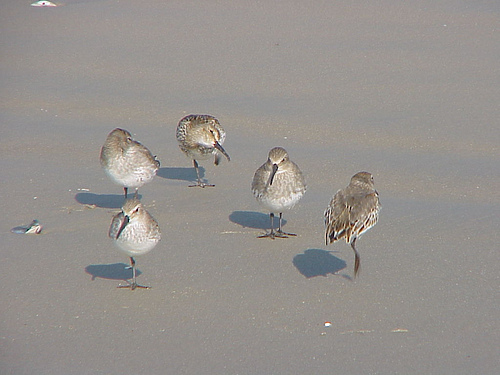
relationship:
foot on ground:
[198, 175, 231, 194] [36, 40, 496, 359]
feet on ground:
[244, 214, 291, 237] [36, 40, 496, 359]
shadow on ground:
[226, 193, 287, 244] [36, 40, 496, 359]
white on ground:
[317, 315, 402, 367] [36, 40, 496, 359]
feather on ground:
[19, 198, 64, 244] [36, 40, 496, 359]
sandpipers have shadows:
[97, 76, 391, 247] [171, 154, 323, 264]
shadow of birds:
[226, 193, 287, 244] [79, 75, 371, 241]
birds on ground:
[79, 75, 371, 241] [36, 40, 496, 359]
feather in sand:
[19, 198, 64, 244] [89, 60, 336, 139]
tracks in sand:
[58, 188, 112, 240] [89, 60, 336, 139]